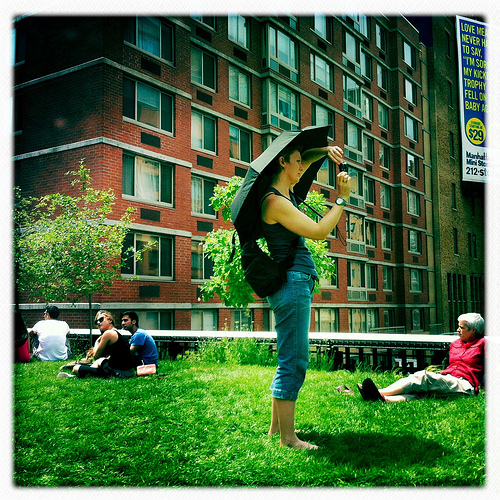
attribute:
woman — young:
[255, 143, 352, 454]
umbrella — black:
[225, 123, 333, 249]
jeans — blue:
[266, 269, 315, 403]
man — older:
[357, 310, 484, 409]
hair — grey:
[457, 310, 485, 335]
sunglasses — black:
[91, 317, 108, 325]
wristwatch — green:
[333, 199, 347, 209]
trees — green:
[17, 156, 158, 350]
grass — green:
[14, 351, 487, 483]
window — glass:
[120, 149, 180, 209]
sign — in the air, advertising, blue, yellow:
[453, 14, 485, 187]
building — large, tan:
[422, 13, 490, 336]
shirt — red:
[440, 336, 485, 398]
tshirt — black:
[258, 189, 326, 281]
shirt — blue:
[122, 328, 159, 368]